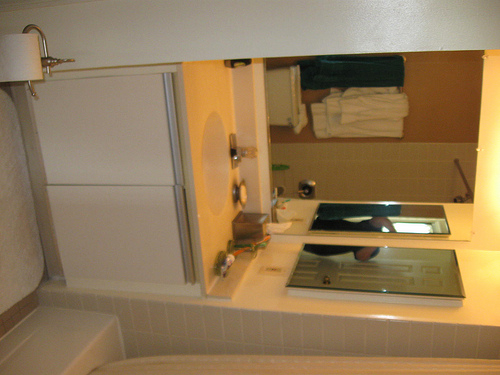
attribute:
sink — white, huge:
[178, 59, 260, 302]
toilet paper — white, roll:
[0, 31, 46, 84]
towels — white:
[308, 58, 401, 145]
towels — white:
[309, 89, 410, 146]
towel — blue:
[295, 56, 404, 91]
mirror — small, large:
[262, 52, 489, 246]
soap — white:
[240, 185, 248, 205]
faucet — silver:
[229, 133, 255, 179]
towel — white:
[337, 93, 409, 123]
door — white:
[28, 71, 189, 189]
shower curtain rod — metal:
[452, 153, 478, 205]